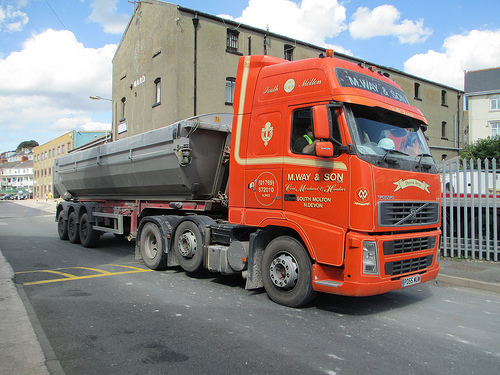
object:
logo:
[392, 178, 431, 194]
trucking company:
[287, 173, 345, 184]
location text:
[284, 183, 345, 209]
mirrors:
[309, 104, 333, 140]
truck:
[49, 50, 441, 308]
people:
[293, 123, 319, 154]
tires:
[172, 220, 202, 272]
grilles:
[379, 199, 440, 226]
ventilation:
[379, 199, 440, 228]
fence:
[440, 154, 499, 264]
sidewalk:
[438, 257, 499, 289]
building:
[110, 0, 464, 162]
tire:
[258, 235, 317, 308]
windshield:
[345, 104, 435, 169]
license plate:
[402, 275, 422, 289]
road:
[0, 200, 500, 375]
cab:
[227, 54, 443, 266]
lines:
[37, 270, 79, 279]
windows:
[151, 77, 162, 108]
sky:
[0, 0, 500, 153]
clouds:
[0, 28, 112, 94]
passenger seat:
[294, 118, 306, 140]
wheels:
[76, 212, 92, 247]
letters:
[287, 174, 294, 181]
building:
[464, 69, 499, 145]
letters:
[141, 76, 145, 83]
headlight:
[358, 239, 380, 276]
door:
[280, 99, 342, 223]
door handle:
[284, 193, 298, 202]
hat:
[376, 137, 395, 151]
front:
[345, 82, 441, 298]